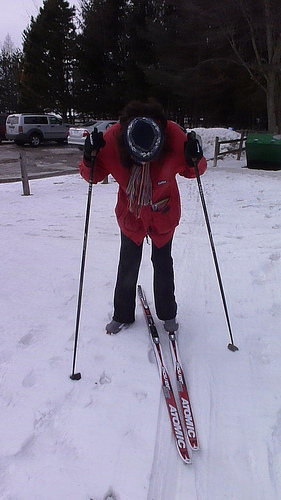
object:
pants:
[111, 228, 177, 323]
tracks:
[146, 403, 234, 496]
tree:
[136, 0, 280, 133]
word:
[180, 395, 196, 438]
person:
[78, 95, 207, 334]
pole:
[191, 161, 239, 352]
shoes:
[161, 318, 179, 334]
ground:
[0, 162, 281, 498]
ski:
[136, 283, 191, 463]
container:
[244, 130, 280, 171]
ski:
[168, 321, 200, 451]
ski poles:
[70, 126, 99, 381]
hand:
[83, 131, 106, 168]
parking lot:
[0, 119, 96, 191]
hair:
[115, 97, 175, 170]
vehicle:
[5, 112, 69, 147]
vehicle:
[66, 120, 121, 151]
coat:
[78, 116, 207, 250]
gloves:
[82, 131, 107, 168]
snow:
[0, 128, 281, 499]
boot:
[161, 316, 180, 334]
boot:
[105, 318, 125, 334]